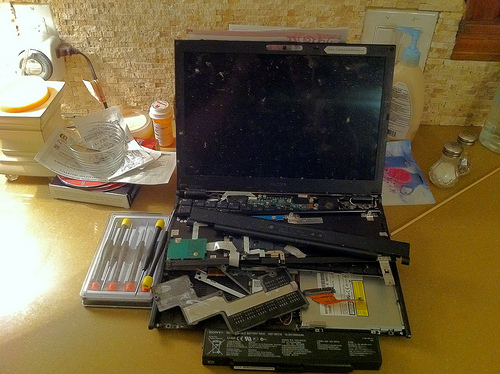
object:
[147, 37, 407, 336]
computer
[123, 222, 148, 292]
tools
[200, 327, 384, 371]
battery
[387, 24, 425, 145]
bottle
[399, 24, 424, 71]
pump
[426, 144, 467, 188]
salt shaker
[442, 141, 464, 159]
top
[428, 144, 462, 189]
pepper shaker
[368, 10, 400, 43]
light switch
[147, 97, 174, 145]
medicine bottle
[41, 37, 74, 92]
plugin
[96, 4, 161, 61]
wall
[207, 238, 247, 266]
parts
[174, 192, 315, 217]
keyboard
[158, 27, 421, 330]
laptop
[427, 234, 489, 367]
surface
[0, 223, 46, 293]
light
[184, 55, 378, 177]
screen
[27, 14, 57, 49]
outlet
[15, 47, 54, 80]
timer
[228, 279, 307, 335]
hard drive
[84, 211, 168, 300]
box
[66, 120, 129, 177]
bowl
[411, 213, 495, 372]
counter top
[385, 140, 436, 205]
paper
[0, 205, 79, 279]
table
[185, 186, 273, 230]
apart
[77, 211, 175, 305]
kit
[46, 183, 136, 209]
book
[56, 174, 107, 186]
discs